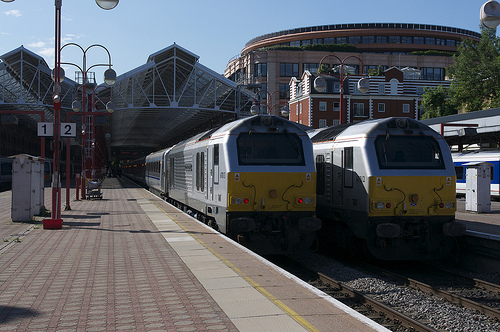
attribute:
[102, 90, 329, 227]
train — boarding, blue, track, station, passenger, yellow, big, commuter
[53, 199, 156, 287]
brick — decorative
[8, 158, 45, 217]
box — white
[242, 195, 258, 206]
ligh — red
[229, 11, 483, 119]
building — large, white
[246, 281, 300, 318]
line — yellow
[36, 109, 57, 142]
sign — 1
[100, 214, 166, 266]
walkway — square, concrete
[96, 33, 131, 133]
pole — light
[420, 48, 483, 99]
tree — green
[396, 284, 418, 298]
rock — track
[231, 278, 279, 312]
stripe — yellow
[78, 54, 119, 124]
lamp — red, street